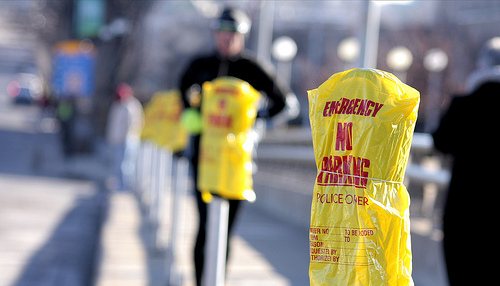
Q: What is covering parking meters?
A: Yellow bags.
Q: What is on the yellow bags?
A: Red letters.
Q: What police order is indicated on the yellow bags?
A: Emergency, No Parking.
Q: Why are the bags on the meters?
A: So people will not use them and be advised that there is no parking there. .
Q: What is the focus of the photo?
A: The bags on the meters.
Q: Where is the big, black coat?
A: On a person, passing the row of meters.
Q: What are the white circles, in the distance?
A: Streetlights.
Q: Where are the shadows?
A: On the sidewalk, on either side of the parking meters..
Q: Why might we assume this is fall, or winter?
A: Pedestrians appear to be dressed warmly, and in outerwear.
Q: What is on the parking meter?
A: Yellow cover.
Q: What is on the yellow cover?
A: Red writing.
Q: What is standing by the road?
A: A man.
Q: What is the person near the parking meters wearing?
A: A black uniform.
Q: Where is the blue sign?
A: Near the road.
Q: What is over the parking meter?
A: A yellow plastic bag.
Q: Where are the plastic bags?
A: Over the parking meters.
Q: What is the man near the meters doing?
A: Jogging.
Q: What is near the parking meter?
A: A person.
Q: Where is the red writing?
A: On the plastic cover.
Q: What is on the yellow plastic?
A: Red writing.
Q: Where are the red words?
A: The bag.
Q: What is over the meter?
A: Plastic bag.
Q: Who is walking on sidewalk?
A: A person.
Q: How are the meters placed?
A: In a row.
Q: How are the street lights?
A: In a row.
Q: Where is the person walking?
A: Sidewalk.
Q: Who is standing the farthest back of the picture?
A: A guy in a red hat.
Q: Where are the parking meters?
A: Under the yellow "no parking" bags.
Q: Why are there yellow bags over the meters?
A: Police order.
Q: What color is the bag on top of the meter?
A: Yellow.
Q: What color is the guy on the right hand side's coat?
A: Black.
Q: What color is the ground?
A: Whitish-grey.